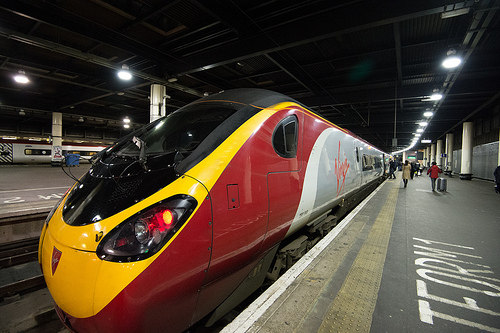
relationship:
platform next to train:
[220, 169, 499, 332] [37, 86, 395, 332]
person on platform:
[426, 157, 442, 196] [220, 169, 499, 332]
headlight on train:
[96, 192, 196, 260] [37, 86, 395, 332]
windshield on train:
[101, 99, 243, 167] [37, 86, 395, 332]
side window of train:
[272, 112, 299, 159] [37, 86, 395, 332]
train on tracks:
[37, 86, 395, 332] [0, 236, 73, 332]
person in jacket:
[426, 157, 442, 196] [427, 164, 443, 180]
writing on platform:
[412, 235, 499, 332] [220, 169, 499, 332]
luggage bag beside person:
[437, 175, 448, 194] [426, 157, 442, 196]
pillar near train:
[429, 142, 437, 170] [37, 86, 395, 332]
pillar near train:
[435, 136, 443, 171] [37, 86, 395, 332]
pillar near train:
[443, 131, 455, 176] [37, 86, 395, 332]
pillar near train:
[460, 121, 474, 182] [37, 86, 395, 332]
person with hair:
[399, 159, 413, 189] [403, 159, 411, 166]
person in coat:
[399, 159, 413, 189] [403, 162, 413, 181]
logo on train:
[49, 245, 62, 275] [37, 86, 395, 332]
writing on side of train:
[331, 139, 352, 197] [37, 86, 395, 332]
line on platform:
[317, 169, 404, 330] [220, 169, 499, 332]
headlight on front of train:
[96, 192, 196, 260] [37, 86, 395, 332]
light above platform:
[429, 90, 441, 104] [220, 169, 499, 332]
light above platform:
[422, 110, 433, 121] [220, 169, 499, 332]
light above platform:
[418, 120, 429, 130] [220, 169, 499, 332]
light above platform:
[416, 127, 424, 136] [220, 169, 499, 332]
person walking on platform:
[426, 157, 442, 196] [220, 169, 499, 332]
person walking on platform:
[399, 159, 413, 189] [220, 169, 499, 332]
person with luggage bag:
[426, 157, 442, 196] [437, 175, 448, 194]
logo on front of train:
[49, 245, 62, 275] [37, 86, 395, 332]